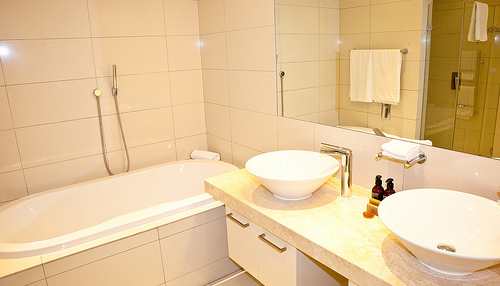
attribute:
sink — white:
[244, 148, 341, 202]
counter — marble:
[204, 167, 499, 285]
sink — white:
[377, 187, 498, 274]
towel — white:
[349, 48, 402, 105]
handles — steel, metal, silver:
[227, 209, 287, 253]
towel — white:
[466, 1, 490, 45]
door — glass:
[454, 1, 493, 156]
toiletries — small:
[362, 174, 395, 222]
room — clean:
[1, 1, 498, 284]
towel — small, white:
[190, 148, 220, 162]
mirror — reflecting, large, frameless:
[272, 2, 498, 159]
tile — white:
[89, 34, 171, 78]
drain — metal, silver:
[437, 240, 456, 254]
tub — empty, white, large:
[0, 158, 244, 284]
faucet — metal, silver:
[321, 142, 353, 198]